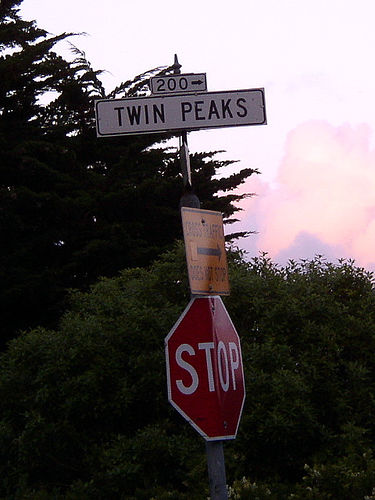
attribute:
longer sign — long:
[91, 87, 266, 139]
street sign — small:
[147, 72, 209, 93]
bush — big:
[247, 262, 366, 495]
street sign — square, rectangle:
[148, 72, 208, 95]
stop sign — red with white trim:
[163, 284, 246, 440]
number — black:
[154, 76, 188, 92]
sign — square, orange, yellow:
[178, 204, 231, 296]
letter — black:
[113, 104, 125, 125]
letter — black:
[125, 104, 142, 125]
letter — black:
[142, 104, 150, 125]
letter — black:
[152, 102, 166, 123]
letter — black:
[178, 100, 192, 122]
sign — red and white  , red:
[161, 290, 247, 443]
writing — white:
[172, 340, 240, 395]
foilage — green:
[0, 235, 375, 496]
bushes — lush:
[0, 231, 375, 497]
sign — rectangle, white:
[94, 85, 267, 138]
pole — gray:
[169, 53, 230, 498]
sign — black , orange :
[178, 200, 233, 299]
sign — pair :
[168, 294, 251, 439]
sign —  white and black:
[98, 68, 270, 140]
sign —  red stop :
[146, 286, 274, 446]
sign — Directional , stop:
[161, 287, 267, 445]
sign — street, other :
[154, 190, 268, 456]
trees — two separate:
[33, 207, 361, 461]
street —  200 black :
[245, 486, 338, 496]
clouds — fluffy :
[246, 108, 319, 212]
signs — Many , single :
[97, 47, 289, 445]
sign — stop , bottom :
[97, 61, 272, 443]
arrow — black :
[196, 238, 232, 267]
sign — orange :
[183, 197, 232, 301]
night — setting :
[7, 0, 350, 490]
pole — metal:
[174, 50, 229, 495]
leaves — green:
[99, 302, 133, 340]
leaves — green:
[309, 392, 352, 415]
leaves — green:
[319, 275, 353, 317]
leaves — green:
[276, 300, 316, 335]